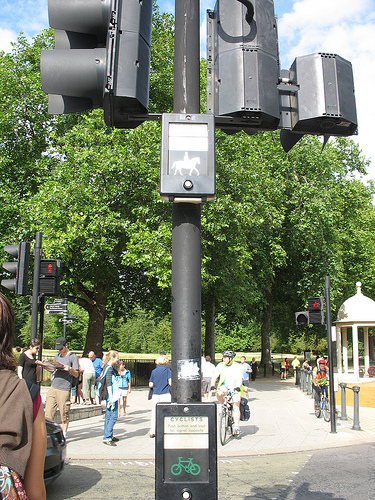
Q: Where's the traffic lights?
A: Roadside.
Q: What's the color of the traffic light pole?
A: Black.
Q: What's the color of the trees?
A: Green.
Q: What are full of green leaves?
A: Trees.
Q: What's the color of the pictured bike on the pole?
A: Green.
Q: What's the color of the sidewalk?
A: Grey.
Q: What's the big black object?
A: Traffic light.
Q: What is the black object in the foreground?
A: Street light.